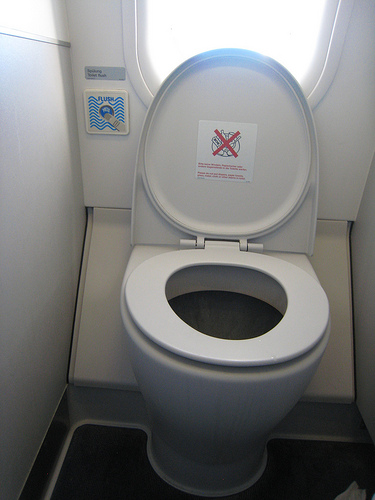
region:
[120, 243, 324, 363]
the toilet seat is down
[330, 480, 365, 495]
paper on the ground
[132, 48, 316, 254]
toilet lid is up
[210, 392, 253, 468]
stains on the toilet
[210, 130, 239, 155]
a red X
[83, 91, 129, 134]
blue and white flush button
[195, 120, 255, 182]
a sticker on the lid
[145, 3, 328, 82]
the bathroom window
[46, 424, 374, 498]
the floor is dark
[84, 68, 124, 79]
a small gray sign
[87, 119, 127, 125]
Small blue cheveron pattern on a sign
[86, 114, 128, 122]
Small blue cheveron pattern on a sign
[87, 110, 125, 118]
Small blue cheveron pattern on a sign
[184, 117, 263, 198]
WHite black and red rign on toilet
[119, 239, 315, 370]
Small round toilet sear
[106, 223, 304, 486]
Small white toilet in a small room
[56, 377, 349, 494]
Small grey base board in a bathroom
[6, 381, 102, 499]
Small grey base board in a bathroom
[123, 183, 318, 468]
toilet in the airplane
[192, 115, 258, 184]
Sticker on the lid.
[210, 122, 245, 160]
Red X on sticker.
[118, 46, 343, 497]
white toilet in the room.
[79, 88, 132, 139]
flush button on the wall.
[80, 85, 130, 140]
blue coloring on the button.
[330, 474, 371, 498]
White paper on the floor.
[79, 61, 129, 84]
Gray sticker on the wall.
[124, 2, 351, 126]
Window behind the toilet.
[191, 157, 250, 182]
Red letters on the sticker.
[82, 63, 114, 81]
Black lettering on the sticker.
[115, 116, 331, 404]
toilet in the airplane